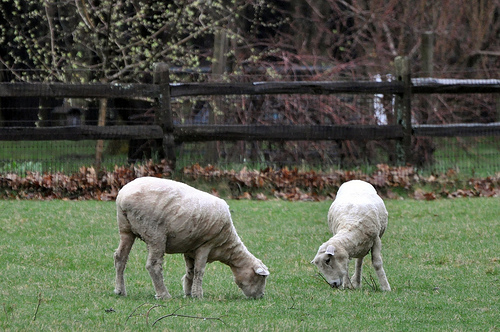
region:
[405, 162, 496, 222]
fallen leaves on grass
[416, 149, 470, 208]
fallen leaves on grass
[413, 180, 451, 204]
fallen leaves on grass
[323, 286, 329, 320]
The grass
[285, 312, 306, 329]
The grass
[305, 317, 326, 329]
The grass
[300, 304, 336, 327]
The grass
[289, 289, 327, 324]
The grass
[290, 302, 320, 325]
The grass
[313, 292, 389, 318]
The grass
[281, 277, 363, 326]
The grass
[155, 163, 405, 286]
two animals on the grass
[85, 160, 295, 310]
white animal on the grass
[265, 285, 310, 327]
green grass under the animals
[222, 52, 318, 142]
fence in the background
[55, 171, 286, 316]
animal eating the grass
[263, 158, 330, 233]
leaves on the fence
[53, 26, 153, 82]
tree behind the fence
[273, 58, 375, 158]
brown fence behind animals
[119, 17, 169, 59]
leaves on the tree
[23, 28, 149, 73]
branches on the tree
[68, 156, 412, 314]
two white sheep with short hair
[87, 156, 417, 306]
two animals grazing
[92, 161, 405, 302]
two sheep eating grass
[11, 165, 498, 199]
fall leaves up against the fence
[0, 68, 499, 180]
a wooden fence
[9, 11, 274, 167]
the tree with green leaves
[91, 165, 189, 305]
the sheep's rear end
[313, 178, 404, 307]
The sheep who has a visible eye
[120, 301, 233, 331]
a stick in the grass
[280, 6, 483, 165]
trees that have lost their leaves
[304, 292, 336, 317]
the grass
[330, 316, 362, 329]
the grass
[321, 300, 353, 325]
the grass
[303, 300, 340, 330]
the grass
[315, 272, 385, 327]
the grass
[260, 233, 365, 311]
the grass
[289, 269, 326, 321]
the grass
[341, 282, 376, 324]
the grass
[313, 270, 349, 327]
the grass